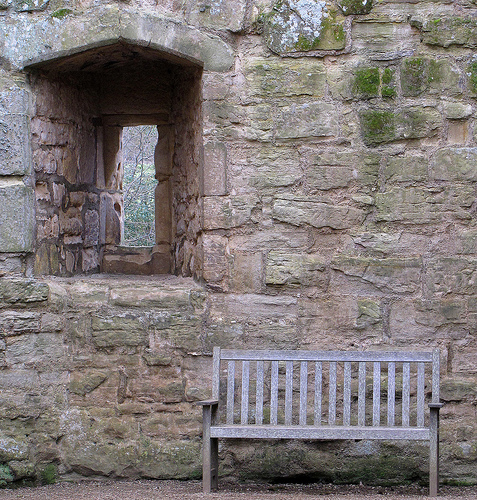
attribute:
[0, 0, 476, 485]
wall — stone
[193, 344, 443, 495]
bench — back of